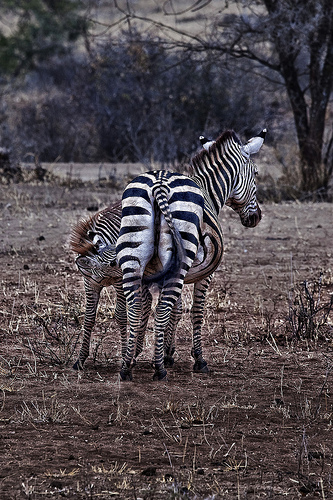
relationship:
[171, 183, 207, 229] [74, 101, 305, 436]
stripes on zebra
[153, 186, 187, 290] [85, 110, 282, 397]
tail on zebra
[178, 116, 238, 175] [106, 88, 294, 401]
comb on zebra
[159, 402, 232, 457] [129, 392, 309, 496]
twigs on ground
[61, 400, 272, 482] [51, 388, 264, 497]
dirt on ground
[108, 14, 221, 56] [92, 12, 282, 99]
branches on tree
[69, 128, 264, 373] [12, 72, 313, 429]
mother in field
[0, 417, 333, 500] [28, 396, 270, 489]
bush on ground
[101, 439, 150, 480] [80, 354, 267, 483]
bush on ground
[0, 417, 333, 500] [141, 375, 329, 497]
bush on ground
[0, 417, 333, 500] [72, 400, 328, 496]
bush on ground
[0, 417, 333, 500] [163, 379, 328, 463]
bush on ground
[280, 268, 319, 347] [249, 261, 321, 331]
bush on ground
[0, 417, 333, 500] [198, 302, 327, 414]
bush on ground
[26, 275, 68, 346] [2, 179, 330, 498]
brush on ground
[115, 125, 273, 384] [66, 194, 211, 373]
zebra feeds young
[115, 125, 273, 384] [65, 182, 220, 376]
zebra with young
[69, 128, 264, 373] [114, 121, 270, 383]
mother feeds from mother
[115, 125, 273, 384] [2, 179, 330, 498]
zebra stands still on ground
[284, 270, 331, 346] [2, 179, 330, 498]
thistle grows from ground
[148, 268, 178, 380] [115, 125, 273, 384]
leg on zebra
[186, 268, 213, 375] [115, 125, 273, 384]
leg on zebra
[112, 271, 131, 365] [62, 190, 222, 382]
leg on zebra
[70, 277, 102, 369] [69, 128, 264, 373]
leg on mother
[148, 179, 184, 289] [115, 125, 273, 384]
tail on zebra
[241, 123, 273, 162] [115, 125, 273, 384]
ear on zebra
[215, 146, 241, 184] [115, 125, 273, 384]
stripes on zebra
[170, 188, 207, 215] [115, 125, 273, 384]
stripes on zebra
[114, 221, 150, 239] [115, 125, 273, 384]
stripes on zebra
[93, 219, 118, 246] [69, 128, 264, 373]
stripes on mother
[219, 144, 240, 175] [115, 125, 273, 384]
stripes on zebra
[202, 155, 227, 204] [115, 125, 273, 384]
stripes on zebra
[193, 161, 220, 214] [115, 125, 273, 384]
stripes on zebra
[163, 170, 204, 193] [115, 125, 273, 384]
stripes on zebra